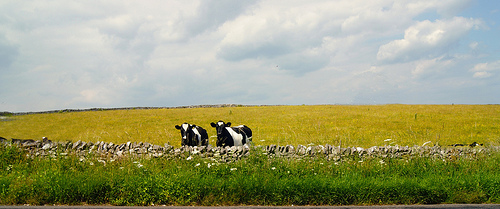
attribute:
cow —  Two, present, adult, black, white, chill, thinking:
[210, 116, 254, 148]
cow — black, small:
[173, 120, 209, 150]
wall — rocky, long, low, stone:
[0, 137, 500, 170]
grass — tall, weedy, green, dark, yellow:
[0, 157, 499, 203]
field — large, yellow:
[0, 104, 500, 144]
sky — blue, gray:
[0, 1, 500, 104]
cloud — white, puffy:
[374, 16, 476, 67]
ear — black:
[226, 121, 232, 128]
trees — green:
[0, 105, 139, 117]